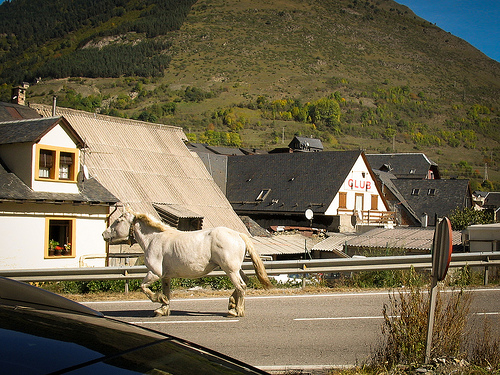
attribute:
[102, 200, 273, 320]
pony — white, running, tan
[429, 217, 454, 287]
sign — circular, red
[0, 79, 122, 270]
building — white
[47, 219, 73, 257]
window — tan, yellow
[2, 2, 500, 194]
mountain — behind, green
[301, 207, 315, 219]
dish — white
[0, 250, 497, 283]
railing — silver, iron, metal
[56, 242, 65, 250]
plant — red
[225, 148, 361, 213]
roof — gray, black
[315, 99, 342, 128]
tree — green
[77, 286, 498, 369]
road — grey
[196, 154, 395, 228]
house — behind, white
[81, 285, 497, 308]
line — white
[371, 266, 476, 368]
bush — dead, green